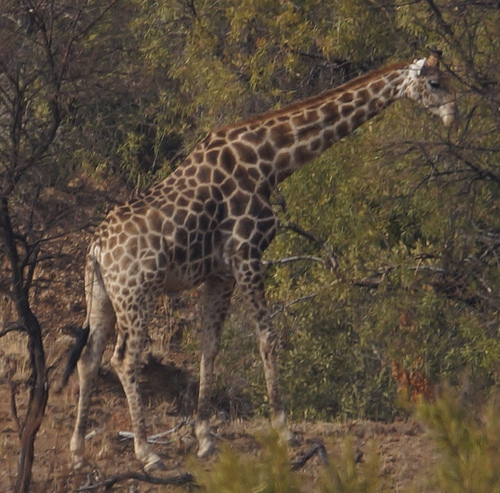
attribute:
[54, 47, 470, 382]
giraffe — spotted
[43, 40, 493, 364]
giraffe — spotted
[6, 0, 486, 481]
photograph — unfocused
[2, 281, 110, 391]
tail — long, black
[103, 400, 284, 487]
branch — broken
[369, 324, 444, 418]
leaves — dead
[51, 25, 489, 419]
giraffe — wild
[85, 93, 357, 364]
fur — brown, white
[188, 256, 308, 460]
legs — long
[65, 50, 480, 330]
tree — leafy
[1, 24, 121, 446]
tree — dead, brown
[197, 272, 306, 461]
legs — long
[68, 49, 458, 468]
giraffe — big, body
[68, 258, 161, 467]
legs — rear, long